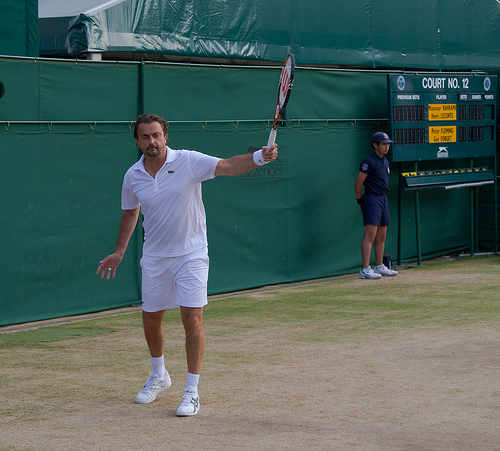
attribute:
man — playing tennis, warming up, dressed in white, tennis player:
[92, 114, 277, 417]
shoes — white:
[135, 370, 200, 415]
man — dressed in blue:
[354, 132, 400, 278]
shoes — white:
[357, 261, 396, 280]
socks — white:
[150, 352, 200, 385]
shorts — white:
[139, 254, 211, 313]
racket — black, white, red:
[266, 53, 294, 149]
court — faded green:
[1, 1, 496, 450]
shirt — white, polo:
[120, 150, 221, 260]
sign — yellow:
[428, 102, 457, 122]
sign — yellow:
[427, 125, 455, 142]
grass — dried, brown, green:
[0, 240, 499, 451]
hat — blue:
[370, 131, 392, 145]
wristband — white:
[251, 148, 269, 165]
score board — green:
[385, 70, 497, 264]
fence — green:
[3, 53, 496, 328]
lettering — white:
[397, 74, 493, 101]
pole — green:
[135, 61, 146, 295]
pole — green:
[383, 73, 391, 133]